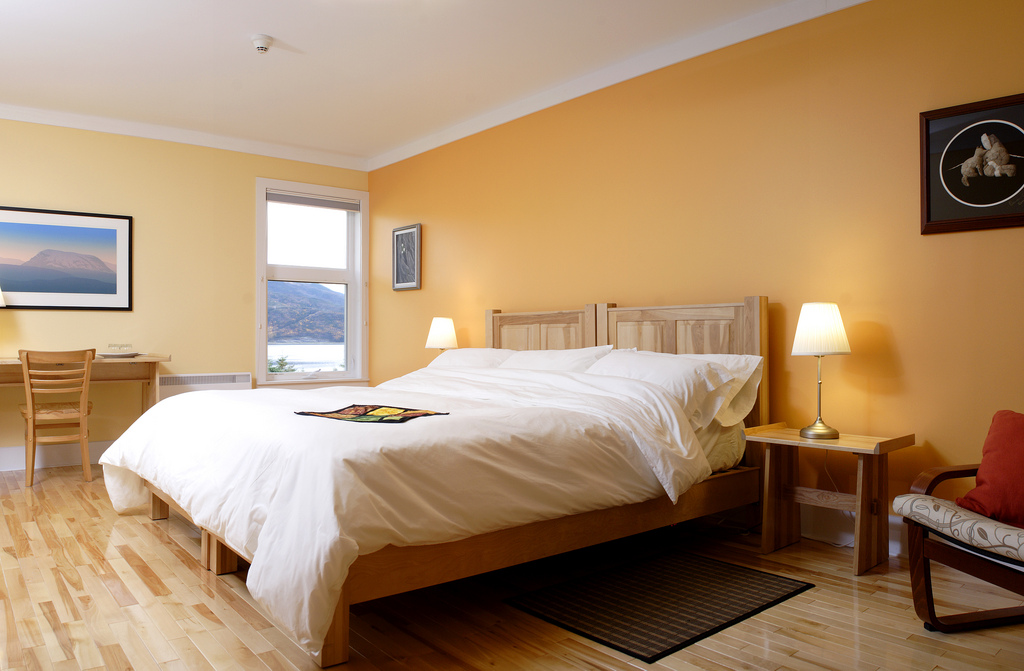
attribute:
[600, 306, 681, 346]
panel — wood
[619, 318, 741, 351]
panel — wood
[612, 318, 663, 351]
panel — wood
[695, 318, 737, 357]
panel — wood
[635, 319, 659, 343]
panel — wood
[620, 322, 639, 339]
panel — wood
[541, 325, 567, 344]
panel — wood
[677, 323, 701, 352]
panel — wood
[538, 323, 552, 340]
panel — wood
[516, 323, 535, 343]
panel — wood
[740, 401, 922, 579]
stand — night stand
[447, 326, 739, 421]
pillows — white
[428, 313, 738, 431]
pillows — white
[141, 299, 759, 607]
bed — white